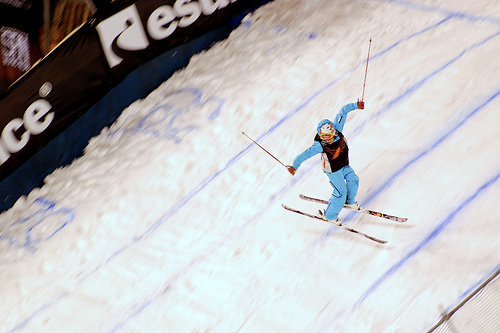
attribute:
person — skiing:
[287, 100, 367, 223]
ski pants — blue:
[322, 165, 361, 220]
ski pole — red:
[360, 31, 374, 98]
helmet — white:
[318, 124, 338, 141]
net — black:
[2, 16, 272, 216]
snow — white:
[2, 0, 499, 331]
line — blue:
[354, 173, 500, 307]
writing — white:
[94, 1, 240, 72]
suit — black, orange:
[314, 131, 351, 173]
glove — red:
[284, 163, 299, 179]